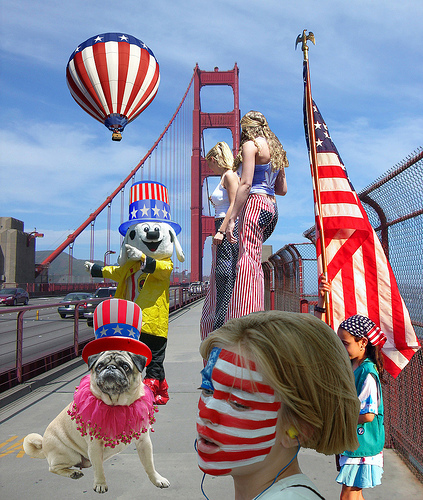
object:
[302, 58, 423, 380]
flag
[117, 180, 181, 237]
hat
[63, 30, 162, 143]
balloon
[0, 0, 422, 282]
clouds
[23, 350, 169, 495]
dog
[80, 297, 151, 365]
hat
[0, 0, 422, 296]
sky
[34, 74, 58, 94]
blue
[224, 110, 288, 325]
woman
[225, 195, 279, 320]
pants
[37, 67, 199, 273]
pole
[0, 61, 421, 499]
bridge